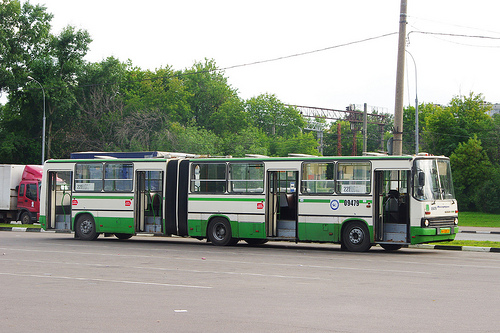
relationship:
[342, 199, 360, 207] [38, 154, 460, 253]
number on side of bus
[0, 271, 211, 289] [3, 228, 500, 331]
line painted on street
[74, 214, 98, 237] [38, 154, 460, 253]
tire attached to bus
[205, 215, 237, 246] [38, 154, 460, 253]
tire attached to bus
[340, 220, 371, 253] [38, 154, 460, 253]
tire attached to bus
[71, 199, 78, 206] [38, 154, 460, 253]
sticker attached to bus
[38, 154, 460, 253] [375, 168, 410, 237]
bus has door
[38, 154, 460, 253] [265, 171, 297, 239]
bus has door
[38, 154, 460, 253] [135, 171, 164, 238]
bus has door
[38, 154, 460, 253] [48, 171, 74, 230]
bus has door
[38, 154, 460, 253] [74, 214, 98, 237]
bus has tire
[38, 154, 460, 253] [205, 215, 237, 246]
bus has tire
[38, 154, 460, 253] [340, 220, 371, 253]
bus has tire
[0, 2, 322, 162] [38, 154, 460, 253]
trees behind bus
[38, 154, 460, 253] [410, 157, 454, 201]
bus has windshield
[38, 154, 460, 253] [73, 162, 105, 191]
bus has window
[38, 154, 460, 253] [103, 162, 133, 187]
bus has window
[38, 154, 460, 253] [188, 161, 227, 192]
bus has window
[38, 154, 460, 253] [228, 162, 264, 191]
bus has window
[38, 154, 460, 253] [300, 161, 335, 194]
bus has window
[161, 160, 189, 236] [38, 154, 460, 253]
connector part of bus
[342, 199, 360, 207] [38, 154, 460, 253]
number printed on bus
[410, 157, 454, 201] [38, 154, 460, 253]
windshield part of bus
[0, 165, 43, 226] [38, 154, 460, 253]
truck behind bus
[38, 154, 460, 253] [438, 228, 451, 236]
bus has license plate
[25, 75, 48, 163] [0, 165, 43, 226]
light pole behind truck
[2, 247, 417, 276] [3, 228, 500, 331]
line painted on street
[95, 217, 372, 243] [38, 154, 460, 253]
bottom section of bus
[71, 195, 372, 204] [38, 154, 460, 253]
stripe painted on bus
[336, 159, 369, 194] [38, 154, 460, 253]
window on side of bus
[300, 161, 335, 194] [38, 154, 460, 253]
window on side of bus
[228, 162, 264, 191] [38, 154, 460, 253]
window on side of bus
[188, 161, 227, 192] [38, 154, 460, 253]
window on side of bus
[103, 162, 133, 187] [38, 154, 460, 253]
window on side of bus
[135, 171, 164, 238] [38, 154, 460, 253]
door on side of bus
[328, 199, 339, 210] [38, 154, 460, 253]
circle printed on bus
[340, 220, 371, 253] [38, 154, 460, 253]
tire part of bus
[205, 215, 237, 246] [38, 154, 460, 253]
tire part of bus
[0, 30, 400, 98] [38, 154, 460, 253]
electric lines over bus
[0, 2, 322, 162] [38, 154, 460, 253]
trees growing behind bus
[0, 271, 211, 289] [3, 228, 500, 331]
line on top of street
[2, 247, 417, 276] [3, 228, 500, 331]
line on top of street